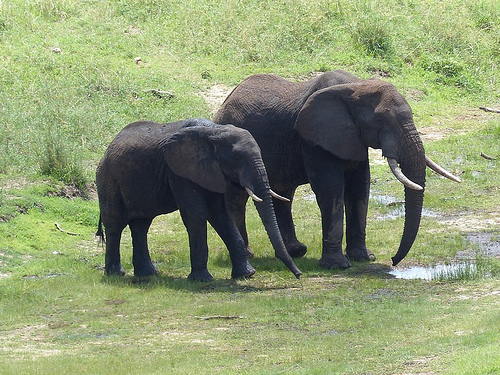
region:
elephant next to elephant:
[90, 66, 461, 284]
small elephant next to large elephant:
[90, 72, 463, 288]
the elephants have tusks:
[246, 187, 291, 204]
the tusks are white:
[241, 152, 461, 212]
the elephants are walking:
[90, 70, 456, 275]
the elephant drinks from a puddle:
[388, 257, 481, 277]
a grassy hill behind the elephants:
[0, 0, 496, 151]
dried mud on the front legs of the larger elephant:
[320, 195, 378, 271]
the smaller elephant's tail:
[95, 200, 106, 245]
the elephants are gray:
[80, 62, 438, 282]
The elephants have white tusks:
[245, 151, 463, 204]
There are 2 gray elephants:
[90, 66, 465, 309]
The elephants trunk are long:
[226, 140, 438, 280]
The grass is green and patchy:
[4, 3, 495, 373]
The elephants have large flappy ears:
[164, 89, 373, 196]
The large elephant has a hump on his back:
[315, 66, 355, 89]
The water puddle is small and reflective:
[390, 249, 491, 294]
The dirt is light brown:
[200, 78, 231, 112]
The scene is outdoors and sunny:
[3, 4, 497, 373]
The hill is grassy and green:
[6, 1, 498, 142]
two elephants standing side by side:
[70, 63, 475, 293]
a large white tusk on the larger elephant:
[380, 149, 425, 195]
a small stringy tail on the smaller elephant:
[88, 213, 112, 256]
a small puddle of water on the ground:
[391, 263, 494, 292]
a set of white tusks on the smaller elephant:
[238, 174, 291, 209]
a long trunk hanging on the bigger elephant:
[387, 188, 427, 268]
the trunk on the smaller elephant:
[255, 203, 307, 278]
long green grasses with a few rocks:
[8, 12, 186, 112]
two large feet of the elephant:
[177, 237, 268, 289]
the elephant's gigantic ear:
[292, 87, 364, 171]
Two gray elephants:
[91, 72, 461, 283]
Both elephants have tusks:
[239, 155, 474, 204]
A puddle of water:
[393, 259, 490, 281]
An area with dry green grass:
[159, 0, 499, 70]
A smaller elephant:
[90, 119, 297, 283]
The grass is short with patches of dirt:
[1, 294, 498, 373]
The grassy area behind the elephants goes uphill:
[2, 0, 301, 293]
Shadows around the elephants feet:
[218, 242, 385, 279]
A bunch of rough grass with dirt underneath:
[30, 142, 96, 205]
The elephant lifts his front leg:
[217, 208, 259, 289]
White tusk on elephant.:
[239, 182, 263, 205]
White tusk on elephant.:
[266, 186, 291, 204]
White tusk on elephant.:
[386, 155, 425, 194]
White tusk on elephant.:
[421, 150, 463, 188]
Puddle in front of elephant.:
[388, 261, 493, 286]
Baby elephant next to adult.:
[86, 116, 305, 286]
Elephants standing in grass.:
[93, 69, 463, 286]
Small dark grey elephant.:
[91, 117, 305, 290]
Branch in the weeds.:
[51, 217, 85, 239]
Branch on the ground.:
[193, 312, 249, 323]